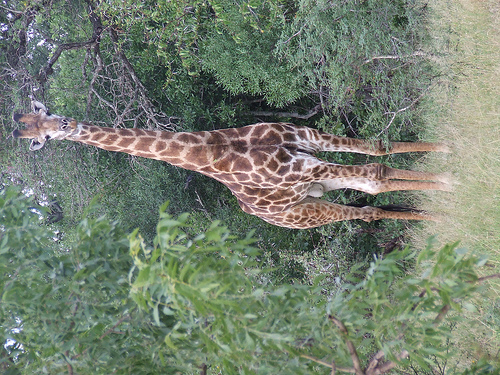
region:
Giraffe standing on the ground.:
[7, 90, 457, 240]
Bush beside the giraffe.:
[127, 203, 499, 373]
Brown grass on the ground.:
[417, 2, 499, 249]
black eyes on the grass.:
[37, 104, 54, 144]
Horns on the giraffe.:
[9, 108, 37, 143]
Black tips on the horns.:
[7, 108, 29, 140]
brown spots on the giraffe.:
[11, 98, 429, 230]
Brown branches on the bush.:
[302, 319, 397, 373]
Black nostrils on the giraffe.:
[59, 117, 70, 132]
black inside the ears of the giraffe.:
[25, 98, 49, 153]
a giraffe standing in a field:
[3, 74, 475, 231]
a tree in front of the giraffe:
[177, 225, 464, 374]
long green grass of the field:
[447, 117, 499, 203]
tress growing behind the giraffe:
[32, 184, 144, 371]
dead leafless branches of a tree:
[1, 13, 196, 126]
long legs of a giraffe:
[304, 119, 466, 236]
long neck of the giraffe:
[79, 97, 254, 200]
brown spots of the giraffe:
[229, 157, 288, 219]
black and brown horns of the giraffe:
[9, 103, 36, 141]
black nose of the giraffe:
[56, 119, 71, 133]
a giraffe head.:
[10, 91, 84, 157]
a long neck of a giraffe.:
[86, 87, 237, 184]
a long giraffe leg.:
[290, 149, 458, 210]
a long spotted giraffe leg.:
[261, 111, 457, 171]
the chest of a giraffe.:
[202, 118, 317, 194]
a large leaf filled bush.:
[109, 197, 486, 373]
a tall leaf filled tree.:
[95, 4, 447, 136]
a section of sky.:
[12, 179, 61, 239]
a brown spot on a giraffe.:
[129, 139, 152, 156]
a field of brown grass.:
[405, 5, 497, 371]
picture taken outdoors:
[5, 1, 497, 362]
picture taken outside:
[5, 3, 499, 358]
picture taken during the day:
[9, 9, 497, 364]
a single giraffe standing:
[11, 89, 487, 297]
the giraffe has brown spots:
[126, 125, 286, 170]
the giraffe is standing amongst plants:
[25, 27, 461, 359]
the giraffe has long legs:
[247, 123, 437, 219]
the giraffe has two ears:
[20, 91, 47, 152]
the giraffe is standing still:
[3, 93, 493, 288]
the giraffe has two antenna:
[9, 109, 28, 141]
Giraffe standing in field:
[10, 92, 470, 234]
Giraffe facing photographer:
[15, 94, 457, 234]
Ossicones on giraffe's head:
[12, 108, 33, 142]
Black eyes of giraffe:
[42, 108, 53, 144]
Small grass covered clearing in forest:
[410, 3, 494, 367]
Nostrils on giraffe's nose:
[60, 116, 70, 134]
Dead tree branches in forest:
[0, 29, 188, 132]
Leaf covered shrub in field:
[121, 198, 498, 373]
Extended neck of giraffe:
[73, 119, 232, 183]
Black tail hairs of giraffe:
[351, 200, 424, 221]